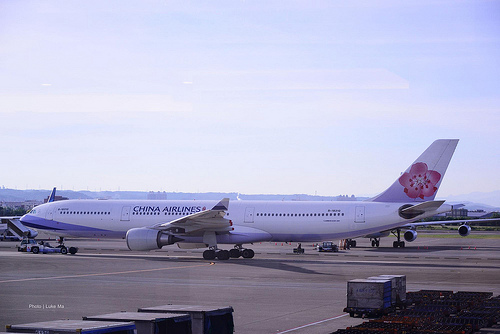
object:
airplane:
[19, 136, 460, 265]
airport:
[5, 1, 500, 332]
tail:
[373, 138, 462, 201]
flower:
[398, 162, 441, 200]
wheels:
[202, 249, 255, 260]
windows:
[59, 211, 110, 215]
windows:
[131, 211, 194, 216]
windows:
[256, 212, 345, 217]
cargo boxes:
[346, 274, 407, 310]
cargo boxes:
[9, 304, 235, 334]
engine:
[126, 227, 176, 251]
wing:
[162, 197, 234, 237]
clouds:
[5, 92, 190, 114]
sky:
[1, 1, 499, 193]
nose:
[18, 214, 38, 229]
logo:
[132, 204, 208, 213]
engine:
[458, 224, 472, 237]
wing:
[411, 218, 499, 227]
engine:
[404, 229, 418, 242]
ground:
[2, 236, 499, 333]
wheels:
[393, 241, 406, 248]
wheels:
[372, 240, 380, 247]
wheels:
[351, 240, 357, 247]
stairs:
[10, 219, 35, 239]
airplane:
[0, 188, 58, 239]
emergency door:
[355, 206, 366, 223]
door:
[120, 205, 130, 221]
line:
[2, 258, 214, 281]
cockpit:
[28, 204, 51, 217]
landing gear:
[203, 244, 255, 260]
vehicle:
[17, 237, 72, 255]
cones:
[417, 245, 429, 250]